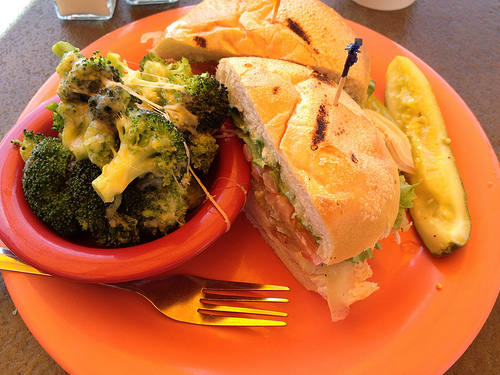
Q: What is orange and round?
A: Plate.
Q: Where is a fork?
A: On the plate.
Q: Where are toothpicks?
A: On the sandwiches.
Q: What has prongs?
A: The fork.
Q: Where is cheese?
A: On broccoli.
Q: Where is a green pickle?
A: On plate.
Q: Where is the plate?
A: On table.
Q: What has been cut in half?
A: Sandwich.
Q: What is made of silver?
A: Fork.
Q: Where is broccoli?
A: In red bowl.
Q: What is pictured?
A: A meal.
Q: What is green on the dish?
A: The broccoli and pickle.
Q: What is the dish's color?
A: Orange.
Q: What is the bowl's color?
A: Red.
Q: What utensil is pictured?
A: A fork.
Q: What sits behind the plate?
A: Salt and pepper shakers.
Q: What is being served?
A: A sandwich.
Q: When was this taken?
A: Maybe lunch time.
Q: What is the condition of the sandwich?
A: Cut into halves.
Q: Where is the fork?
A: On the plate.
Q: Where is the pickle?
A: On the side of the plate.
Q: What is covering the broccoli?
A: Cheese.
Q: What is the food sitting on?
A: A plate.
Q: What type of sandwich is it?
A: A turkey club.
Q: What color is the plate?
A: Orange.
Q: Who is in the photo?
A: No one.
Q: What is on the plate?
A: Food.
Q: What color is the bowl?
A: Red.